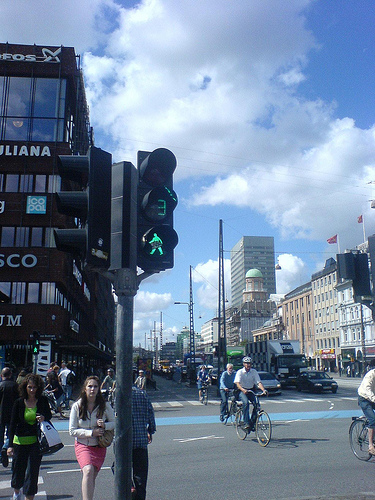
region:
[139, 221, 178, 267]
a green pedestrian light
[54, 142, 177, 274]
street light on the corner of a street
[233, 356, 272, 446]
man with a cap on a bicycle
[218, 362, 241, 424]
man with white hair on a bicycle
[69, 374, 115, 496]
young woman crossing a street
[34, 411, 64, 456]
woman holding a black and white bag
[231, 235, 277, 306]
a skyscraper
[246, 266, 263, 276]
a green dome on top of a building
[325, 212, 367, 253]
two flags on white poles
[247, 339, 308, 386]
a black and white truck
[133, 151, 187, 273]
a traffic light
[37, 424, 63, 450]
women holding a bag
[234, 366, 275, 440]
man riding a bike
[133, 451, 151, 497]
person wearing pants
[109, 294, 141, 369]
a pole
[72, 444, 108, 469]
a pink skirt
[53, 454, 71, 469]
shadows on the ground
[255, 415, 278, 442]
front tire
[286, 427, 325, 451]
shadow on the ground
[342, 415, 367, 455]
back of the bikes tire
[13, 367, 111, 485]
people crossing the street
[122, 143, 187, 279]
traffic light on the pole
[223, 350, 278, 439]
man on the bicycle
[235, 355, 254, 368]
man wearing helmet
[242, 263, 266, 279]
the dome on the building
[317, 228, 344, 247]
the flag on the building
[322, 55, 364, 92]
the clear blue sky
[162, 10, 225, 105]
cloud in the sky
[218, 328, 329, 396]
cars on the street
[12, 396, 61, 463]
woman with black and white bag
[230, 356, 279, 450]
person riding a bike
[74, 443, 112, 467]
women wearing a pink skirt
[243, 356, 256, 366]
a helmet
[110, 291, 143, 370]
a metal pole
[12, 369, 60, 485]
a women walking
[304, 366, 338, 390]
a car on the street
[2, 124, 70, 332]
a building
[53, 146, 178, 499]
A traffic light style crosswalk sign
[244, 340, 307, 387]
A black and white checkered semi truck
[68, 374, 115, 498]
A woman in a white jacket and pink skirt crossing the street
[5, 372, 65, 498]
A woman in black and green carrying a bag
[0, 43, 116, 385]
A multistory brown and white building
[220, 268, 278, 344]
A light brown building with a light green dome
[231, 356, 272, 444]
An old man in white on a bike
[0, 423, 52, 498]
A white painted crosswalk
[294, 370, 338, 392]
A black car about to cross the street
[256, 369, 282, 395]
A silver car about to cross the street